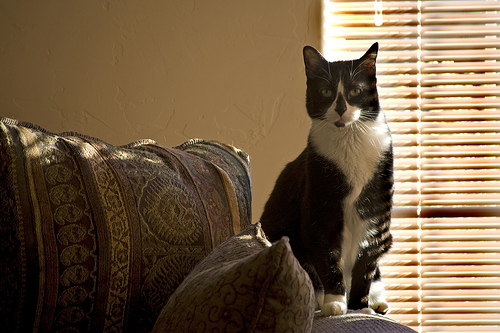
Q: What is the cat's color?
A: Black and white.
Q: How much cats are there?
A: One.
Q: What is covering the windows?
A: Blinds.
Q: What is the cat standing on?
A: Couch.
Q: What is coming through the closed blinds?
A: Sunlight.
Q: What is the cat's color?
A: Black and white.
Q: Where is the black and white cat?
A: On the couch's arm.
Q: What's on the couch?
A: Pillows.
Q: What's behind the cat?
A: Window.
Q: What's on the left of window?
A: Beige plaster wall.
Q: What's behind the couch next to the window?
A: The wall.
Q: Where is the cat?
A: On arm of sofa.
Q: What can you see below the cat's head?
A: The white neck.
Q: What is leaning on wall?
A: Orange and burgundy pillow.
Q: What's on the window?
A: Light brown shades.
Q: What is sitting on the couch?
A: Cat.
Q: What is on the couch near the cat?
A: Pillow.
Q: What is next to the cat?
A: Window.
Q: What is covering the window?
A: Blinds.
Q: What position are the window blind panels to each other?
A: Parallel.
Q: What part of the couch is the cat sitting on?
A: Arm rest.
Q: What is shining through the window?
A: Sunlight.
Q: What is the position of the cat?
A: Sitting.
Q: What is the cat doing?
A: Sitting.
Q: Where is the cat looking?
A: At camera.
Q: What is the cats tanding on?
A: A large couch.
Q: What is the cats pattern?
A: Black and white spots.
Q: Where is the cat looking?
A: The camera.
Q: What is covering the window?
A: Blinds.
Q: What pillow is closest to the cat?
A: The couch pillow.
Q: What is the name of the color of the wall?
A: Beige.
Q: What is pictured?
A: A cat.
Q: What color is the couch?
A: Brown.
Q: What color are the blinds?
A: Cream.